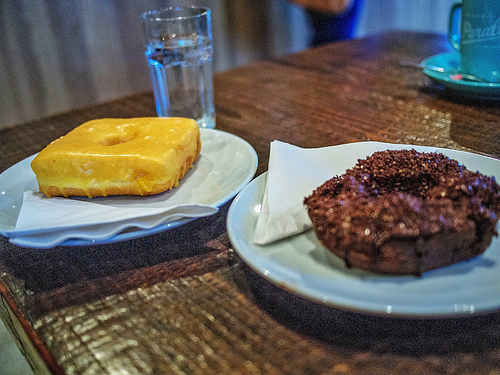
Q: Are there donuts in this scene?
A: Yes, there is a donut.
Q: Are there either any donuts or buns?
A: Yes, there is a donut.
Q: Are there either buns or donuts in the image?
A: Yes, there is a donut.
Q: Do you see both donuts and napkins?
A: Yes, there are both a donut and a napkin.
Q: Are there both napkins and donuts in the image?
A: Yes, there are both a donut and a napkin.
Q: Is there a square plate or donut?
A: Yes, there is a square donut.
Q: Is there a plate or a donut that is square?
A: Yes, the donut is square.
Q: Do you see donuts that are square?
A: Yes, there is a square donut.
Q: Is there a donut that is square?
A: Yes, there is a donut that is square.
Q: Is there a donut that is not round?
A: Yes, there is a square donut.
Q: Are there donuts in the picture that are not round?
A: Yes, there is a square donut.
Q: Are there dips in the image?
A: No, there are no dips.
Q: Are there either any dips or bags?
A: No, there are no dips or bags.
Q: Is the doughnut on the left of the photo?
A: Yes, the doughnut is on the left of the image.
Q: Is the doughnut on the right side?
A: No, the doughnut is on the left of the image.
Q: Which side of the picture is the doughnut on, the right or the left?
A: The doughnut is on the left of the image.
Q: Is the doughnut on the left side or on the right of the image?
A: The doughnut is on the left of the image.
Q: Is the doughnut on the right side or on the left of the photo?
A: The doughnut is on the left of the image.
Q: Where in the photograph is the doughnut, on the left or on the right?
A: The doughnut is on the left of the image.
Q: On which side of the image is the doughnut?
A: The doughnut is on the left of the image.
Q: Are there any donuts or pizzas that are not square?
A: No, there is a donut but it is square.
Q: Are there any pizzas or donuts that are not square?
A: No, there is a donut but it is square.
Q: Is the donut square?
A: Yes, the donut is square.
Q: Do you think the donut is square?
A: Yes, the donut is square.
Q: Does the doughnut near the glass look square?
A: Yes, the donut is square.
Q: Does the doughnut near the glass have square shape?
A: Yes, the donut is square.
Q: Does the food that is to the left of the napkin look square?
A: Yes, the donut is square.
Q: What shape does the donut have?
A: The donut has square shape.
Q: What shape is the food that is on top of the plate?
A: The donut is square.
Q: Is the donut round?
A: No, the donut is square.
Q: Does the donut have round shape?
A: No, the donut is square.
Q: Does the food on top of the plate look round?
A: No, the donut is square.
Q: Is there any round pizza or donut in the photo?
A: No, there is a donut but it is square.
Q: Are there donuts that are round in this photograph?
A: No, there is a donut but it is square.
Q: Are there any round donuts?
A: No, there is a donut but it is square.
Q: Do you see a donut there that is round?
A: No, there is a donut but it is square.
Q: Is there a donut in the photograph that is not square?
A: No, there is a donut but it is square.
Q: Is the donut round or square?
A: The donut is square.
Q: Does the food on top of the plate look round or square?
A: The donut is square.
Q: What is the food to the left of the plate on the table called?
A: The food is a donut.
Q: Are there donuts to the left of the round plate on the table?
A: Yes, there is a donut to the left of the plate.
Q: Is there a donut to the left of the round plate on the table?
A: Yes, there is a donut to the left of the plate.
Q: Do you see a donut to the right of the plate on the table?
A: No, the donut is to the left of the plate.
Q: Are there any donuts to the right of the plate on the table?
A: No, the donut is to the left of the plate.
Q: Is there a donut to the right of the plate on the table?
A: No, the donut is to the left of the plate.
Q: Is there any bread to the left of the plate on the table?
A: No, there is a donut to the left of the plate.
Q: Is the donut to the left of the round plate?
A: Yes, the donut is to the left of the plate.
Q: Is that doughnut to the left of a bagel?
A: No, the doughnut is to the left of the plate.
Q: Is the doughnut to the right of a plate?
A: No, the doughnut is to the left of a plate.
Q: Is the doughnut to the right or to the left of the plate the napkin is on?
A: The doughnut is to the left of the plate.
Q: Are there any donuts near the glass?
A: Yes, there is a donut near the glass.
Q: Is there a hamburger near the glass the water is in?
A: No, there is a donut near the glass.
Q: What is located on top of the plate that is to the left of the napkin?
A: The donut is on top of the plate.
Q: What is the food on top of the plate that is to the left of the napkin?
A: The food is a donut.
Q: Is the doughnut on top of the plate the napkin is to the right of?
A: Yes, the doughnut is on top of the plate.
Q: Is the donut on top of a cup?
A: No, the donut is on top of the plate.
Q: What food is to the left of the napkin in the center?
A: The food is a donut.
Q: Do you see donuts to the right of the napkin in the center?
A: No, the donut is to the left of the napkin.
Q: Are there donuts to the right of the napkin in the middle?
A: No, the donut is to the left of the napkin.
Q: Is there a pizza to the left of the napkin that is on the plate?
A: No, there is a donut to the left of the napkin.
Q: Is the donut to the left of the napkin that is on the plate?
A: Yes, the donut is to the left of the napkin.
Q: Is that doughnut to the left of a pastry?
A: No, the doughnut is to the left of the napkin.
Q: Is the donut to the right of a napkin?
A: No, the donut is to the left of a napkin.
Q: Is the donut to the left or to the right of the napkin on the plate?
A: The donut is to the left of the napkin.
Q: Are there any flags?
A: No, there are no flags.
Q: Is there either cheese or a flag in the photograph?
A: No, there are no flags or cheese.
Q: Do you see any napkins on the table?
A: Yes, there is a napkin on the table.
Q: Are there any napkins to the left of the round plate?
A: Yes, there is a napkin to the left of the plate.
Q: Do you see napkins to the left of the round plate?
A: Yes, there is a napkin to the left of the plate.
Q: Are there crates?
A: No, there are no crates.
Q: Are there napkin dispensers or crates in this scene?
A: No, there are no crates or napkin dispensers.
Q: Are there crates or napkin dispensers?
A: No, there are no crates or napkin dispensers.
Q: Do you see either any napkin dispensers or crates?
A: No, there are no crates or napkin dispensers.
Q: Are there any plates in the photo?
A: Yes, there is a plate.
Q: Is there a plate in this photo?
A: Yes, there is a plate.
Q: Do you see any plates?
A: Yes, there is a plate.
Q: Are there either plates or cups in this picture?
A: Yes, there is a plate.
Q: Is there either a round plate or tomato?
A: Yes, there is a round plate.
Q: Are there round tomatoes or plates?
A: Yes, there is a round plate.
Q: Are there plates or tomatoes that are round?
A: Yes, the plate is round.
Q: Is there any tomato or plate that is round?
A: Yes, the plate is round.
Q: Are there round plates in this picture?
A: Yes, there is a round plate.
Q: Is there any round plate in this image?
A: Yes, there is a round plate.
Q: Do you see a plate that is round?
A: Yes, there is a plate that is round.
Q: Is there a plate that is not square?
A: Yes, there is a round plate.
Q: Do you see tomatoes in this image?
A: No, there are no tomatoes.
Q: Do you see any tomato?
A: No, there are no tomatoes.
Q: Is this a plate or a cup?
A: This is a plate.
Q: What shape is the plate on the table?
A: The plate is round.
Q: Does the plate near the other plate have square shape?
A: No, the plate is round.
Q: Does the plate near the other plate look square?
A: No, the plate is round.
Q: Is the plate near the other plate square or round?
A: The plate is round.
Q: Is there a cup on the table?
A: No, there is a plate on the table.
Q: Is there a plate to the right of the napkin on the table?
A: Yes, there is a plate to the right of the napkin.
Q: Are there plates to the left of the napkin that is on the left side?
A: No, the plate is to the right of the napkin.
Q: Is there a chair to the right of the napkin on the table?
A: No, there is a plate to the right of the napkin.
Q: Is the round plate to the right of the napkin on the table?
A: Yes, the plate is to the right of the napkin.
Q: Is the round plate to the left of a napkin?
A: No, the plate is to the right of a napkin.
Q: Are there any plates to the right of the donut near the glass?
A: Yes, there is a plate to the right of the donut.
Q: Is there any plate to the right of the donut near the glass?
A: Yes, there is a plate to the right of the donut.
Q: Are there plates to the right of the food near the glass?
A: Yes, there is a plate to the right of the donut.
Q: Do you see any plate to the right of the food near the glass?
A: Yes, there is a plate to the right of the donut.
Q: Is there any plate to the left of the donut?
A: No, the plate is to the right of the donut.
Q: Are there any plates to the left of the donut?
A: No, the plate is to the right of the donut.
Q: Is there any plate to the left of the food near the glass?
A: No, the plate is to the right of the donut.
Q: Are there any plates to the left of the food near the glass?
A: No, the plate is to the right of the donut.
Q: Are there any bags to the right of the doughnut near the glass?
A: No, there is a plate to the right of the doughnut.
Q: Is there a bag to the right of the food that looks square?
A: No, there is a plate to the right of the doughnut.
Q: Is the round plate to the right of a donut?
A: Yes, the plate is to the right of a donut.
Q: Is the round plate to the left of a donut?
A: No, the plate is to the right of a donut.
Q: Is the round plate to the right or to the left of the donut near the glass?
A: The plate is to the right of the doughnut.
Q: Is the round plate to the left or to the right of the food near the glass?
A: The plate is to the right of the doughnut.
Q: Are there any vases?
A: No, there are no vases.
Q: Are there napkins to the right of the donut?
A: Yes, there is a napkin to the right of the donut.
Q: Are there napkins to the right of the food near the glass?
A: Yes, there is a napkin to the right of the donut.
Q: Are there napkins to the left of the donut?
A: No, the napkin is to the right of the donut.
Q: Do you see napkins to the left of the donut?
A: No, the napkin is to the right of the donut.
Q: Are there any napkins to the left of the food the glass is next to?
A: No, the napkin is to the right of the donut.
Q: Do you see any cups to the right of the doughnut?
A: No, there is a napkin to the right of the doughnut.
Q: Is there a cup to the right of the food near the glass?
A: No, there is a napkin to the right of the doughnut.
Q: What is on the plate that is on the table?
A: The napkin is on the plate.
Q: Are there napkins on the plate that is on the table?
A: Yes, there is a napkin on the plate.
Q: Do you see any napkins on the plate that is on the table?
A: Yes, there is a napkin on the plate.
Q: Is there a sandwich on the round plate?
A: No, there is a napkin on the plate.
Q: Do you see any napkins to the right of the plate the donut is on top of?
A: Yes, there is a napkin to the right of the plate.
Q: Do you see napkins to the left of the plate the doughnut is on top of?
A: No, the napkin is to the right of the plate.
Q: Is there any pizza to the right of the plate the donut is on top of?
A: No, there is a napkin to the right of the plate.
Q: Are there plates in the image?
A: Yes, there is a plate.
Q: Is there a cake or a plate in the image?
A: Yes, there is a plate.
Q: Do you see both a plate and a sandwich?
A: No, there is a plate but no sandwiches.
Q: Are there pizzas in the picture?
A: No, there are no pizzas.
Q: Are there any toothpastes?
A: No, there are no toothpastes.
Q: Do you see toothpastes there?
A: No, there are no toothpastes.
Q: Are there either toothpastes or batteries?
A: No, there are no toothpastes or batteries.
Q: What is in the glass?
A: The water is in the glass.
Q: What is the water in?
A: The water is in the glass.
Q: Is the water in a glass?
A: Yes, the water is in a glass.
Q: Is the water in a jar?
A: No, the water is in a glass.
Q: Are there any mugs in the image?
A: Yes, there is a mug.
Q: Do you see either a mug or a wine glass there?
A: Yes, there is a mug.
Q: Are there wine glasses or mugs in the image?
A: Yes, there is a mug.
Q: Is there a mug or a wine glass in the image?
A: Yes, there is a mug.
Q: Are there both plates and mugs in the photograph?
A: Yes, there are both a mug and a plate.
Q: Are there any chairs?
A: No, there are no chairs.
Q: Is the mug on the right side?
A: Yes, the mug is on the right of the image.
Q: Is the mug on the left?
A: No, the mug is on the right of the image.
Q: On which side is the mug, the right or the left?
A: The mug is on the right of the image.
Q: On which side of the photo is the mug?
A: The mug is on the right of the image.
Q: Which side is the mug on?
A: The mug is on the right of the image.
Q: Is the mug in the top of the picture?
A: Yes, the mug is in the top of the image.